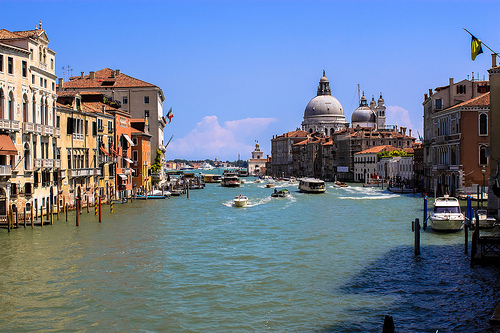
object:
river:
[0, 168, 499, 332]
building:
[53, 68, 165, 188]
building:
[76, 101, 134, 198]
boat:
[229, 198, 249, 206]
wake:
[250, 197, 270, 204]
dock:
[0, 188, 50, 225]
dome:
[303, 94, 345, 116]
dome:
[350, 105, 376, 122]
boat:
[426, 194, 465, 230]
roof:
[56, 67, 158, 88]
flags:
[166, 107, 174, 125]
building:
[56, 101, 115, 211]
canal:
[0, 168, 499, 332]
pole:
[76, 198, 80, 227]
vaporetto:
[297, 177, 327, 193]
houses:
[0, 17, 61, 219]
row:
[0, 28, 168, 225]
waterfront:
[1, 218, 50, 225]